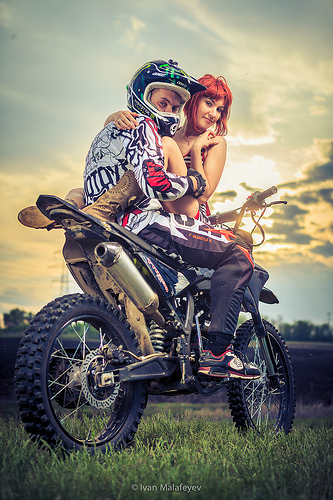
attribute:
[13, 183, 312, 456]
motorcycle — black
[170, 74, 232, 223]
woman — white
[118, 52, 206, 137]
helmet — black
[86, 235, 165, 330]
exhaust — silver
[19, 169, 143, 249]
boots — brown cowboy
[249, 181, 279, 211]
handle — black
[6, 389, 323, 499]
grass — green, long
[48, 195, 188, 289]
sit — black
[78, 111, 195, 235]
shirt — is black, is red, white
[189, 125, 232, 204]
arm — bent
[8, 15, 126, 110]
sky — blue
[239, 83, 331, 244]
sky — cloudy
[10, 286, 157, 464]
tire — black, round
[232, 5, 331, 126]
clouds — white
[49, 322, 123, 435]
spokes — metal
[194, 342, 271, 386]
shoes — red, white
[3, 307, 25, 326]
leaves — green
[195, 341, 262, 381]
shoe — black